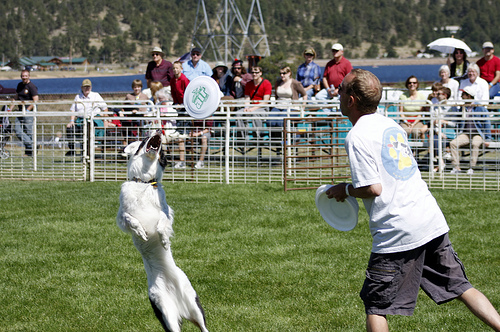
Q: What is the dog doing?
A: Catching the frisbee.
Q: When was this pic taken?
A: During the day.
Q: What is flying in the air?
A: Frisbee.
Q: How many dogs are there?
A: 1.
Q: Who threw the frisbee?
A: The man.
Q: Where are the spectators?
A: In the stands.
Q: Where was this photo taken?
A: At the park.